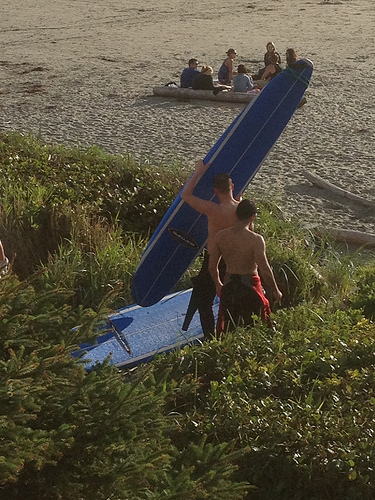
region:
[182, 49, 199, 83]
guy on the beach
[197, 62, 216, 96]
girl sitting on the beach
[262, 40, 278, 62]
girl sitting on the beach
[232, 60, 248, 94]
person sitting on the beach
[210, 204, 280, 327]
guy standing near two surfboards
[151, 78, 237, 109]
log on the beach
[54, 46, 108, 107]
sand on the beach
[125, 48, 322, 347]
Man holding a board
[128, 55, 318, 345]
Man is holding a board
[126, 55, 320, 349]
Man holding a surfboard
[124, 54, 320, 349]
Man is holding a surfboard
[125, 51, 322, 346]
Man holding a blue board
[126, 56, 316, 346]
Man is holding a blue board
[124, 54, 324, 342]
Man holding a blue surfboard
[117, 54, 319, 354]
Man is holding a blue surfboard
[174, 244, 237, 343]
Man wearing a black wet suit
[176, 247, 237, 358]
Man is wearing a black wet suit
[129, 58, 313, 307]
large blue surf board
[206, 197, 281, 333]
male surfer in wet suit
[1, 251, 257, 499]
Green branches on a tree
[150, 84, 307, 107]
log on the beach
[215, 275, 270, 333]
black, red and gray wet suit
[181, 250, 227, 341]
black colored wet suit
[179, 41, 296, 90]
seven people sitting on the beach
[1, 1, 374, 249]
sand on the beach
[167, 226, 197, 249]
logo on a blue surf board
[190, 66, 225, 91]
woman with blond ponytail sitting on beach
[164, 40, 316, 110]
group of people sitting on beach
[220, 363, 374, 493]
bushes covered in green leaves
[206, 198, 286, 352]
man wearing black and red clothing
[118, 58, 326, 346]
man holding long blue surfboard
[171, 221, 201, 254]
company logo on blue surfboard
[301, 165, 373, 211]
large log laying on beach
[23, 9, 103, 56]
tracks in beach sand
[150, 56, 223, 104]
couple leaning on large log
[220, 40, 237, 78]
woman with short blonde hair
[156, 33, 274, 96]
A group of people sitting on a log.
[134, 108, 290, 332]
Two men in wet suits.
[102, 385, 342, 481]
Tall seaside grasses.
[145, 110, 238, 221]
A man carrying a long surfboard.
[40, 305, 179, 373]
A long surfboard sits in the tall grass.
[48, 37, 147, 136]
A sandy beach.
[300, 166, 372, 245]
Driftwood on the beach.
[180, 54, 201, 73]
A man with sunglasses.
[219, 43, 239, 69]
A woman with sunglasses.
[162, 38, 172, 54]
A patch of sand.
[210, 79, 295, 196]
The surfboard is blue.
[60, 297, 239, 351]
A blue surfboard on the ground.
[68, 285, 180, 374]
a blue surf board on the ground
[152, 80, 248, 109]
a log on a sandy beach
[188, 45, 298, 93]
several people sitting on the ground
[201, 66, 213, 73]
a woman with blonde hair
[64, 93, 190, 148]
tracks in the sand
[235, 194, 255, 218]
a man with black hair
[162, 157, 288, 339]
two guys preparing to Surf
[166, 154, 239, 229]
A guy holding the surfboard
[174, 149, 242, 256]
a guy holding a blue surfboard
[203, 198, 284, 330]
a guy with a surf suit half on